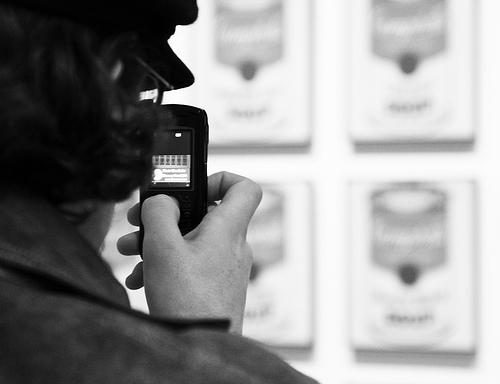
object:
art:
[341, 175, 483, 355]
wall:
[96, 0, 500, 384]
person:
[0, 0, 327, 384]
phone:
[139, 103, 213, 262]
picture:
[148, 131, 193, 188]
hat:
[1, 0, 202, 92]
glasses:
[107, 39, 175, 112]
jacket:
[0, 183, 331, 384]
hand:
[117, 170, 263, 339]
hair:
[0, 7, 181, 207]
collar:
[1, 184, 233, 333]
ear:
[102, 57, 145, 127]